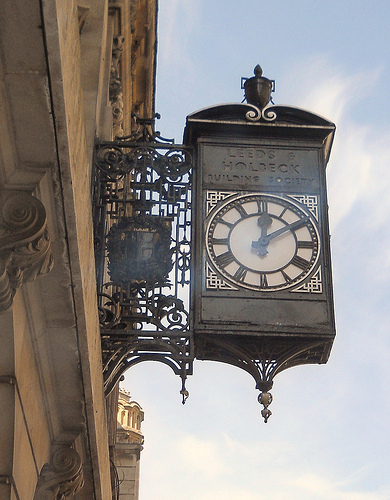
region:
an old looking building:
[0, 1, 168, 496]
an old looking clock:
[96, 61, 348, 428]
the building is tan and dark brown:
[2, 3, 163, 495]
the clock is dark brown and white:
[172, 65, 338, 426]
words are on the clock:
[207, 140, 317, 184]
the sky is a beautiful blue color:
[139, 3, 384, 491]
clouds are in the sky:
[121, 2, 383, 488]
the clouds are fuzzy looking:
[120, 2, 389, 498]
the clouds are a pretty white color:
[126, 4, 380, 486]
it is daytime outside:
[1, 0, 376, 488]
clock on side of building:
[174, 131, 332, 362]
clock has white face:
[202, 198, 307, 311]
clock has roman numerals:
[230, 201, 305, 299]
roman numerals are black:
[203, 171, 304, 297]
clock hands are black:
[219, 181, 295, 270]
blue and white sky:
[223, 29, 366, 107]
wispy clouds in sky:
[158, 279, 345, 498]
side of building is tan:
[4, 293, 101, 450]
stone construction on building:
[5, 296, 59, 468]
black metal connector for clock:
[98, 130, 209, 377]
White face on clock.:
[233, 198, 295, 270]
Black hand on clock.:
[272, 206, 305, 255]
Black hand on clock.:
[248, 203, 270, 262]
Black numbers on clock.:
[213, 201, 298, 308]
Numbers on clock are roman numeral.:
[225, 201, 319, 302]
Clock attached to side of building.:
[108, 175, 302, 317]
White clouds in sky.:
[184, 448, 239, 490]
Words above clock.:
[210, 148, 282, 188]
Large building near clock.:
[19, 40, 108, 291]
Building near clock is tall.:
[58, 21, 166, 190]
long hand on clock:
[266, 217, 320, 242]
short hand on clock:
[256, 208, 272, 235]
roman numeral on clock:
[291, 254, 311, 271]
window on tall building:
[131, 409, 136, 430]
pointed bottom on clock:
[250, 378, 277, 420]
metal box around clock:
[190, 291, 333, 346]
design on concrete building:
[32, 443, 91, 491]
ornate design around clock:
[202, 188, 233, 215]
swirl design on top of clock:
[234, 101, 295, 129]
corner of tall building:
[3, 334, 30, 486]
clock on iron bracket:
[97, 64, 337, 422]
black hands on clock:
[253, 211, 310, 260]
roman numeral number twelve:
[256, 199, 268, 213]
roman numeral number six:
[259, 270, 268, 287]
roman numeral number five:
[281, 268, 291, 283]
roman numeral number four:
[292, 254, 309, 270]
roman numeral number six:
[232, 265, 248, 281]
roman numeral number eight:
[215, 251, 235, 268]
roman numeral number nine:
[213, 235, 229, 243]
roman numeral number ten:
[218, 217, 234, 228]